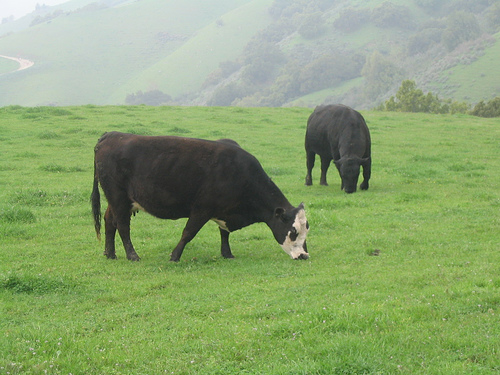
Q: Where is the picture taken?
A: A field.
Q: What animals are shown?
A: Cows.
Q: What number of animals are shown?
A: Two.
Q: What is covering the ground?
A: Grass.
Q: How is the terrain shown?
A: Hilly.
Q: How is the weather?
A: Misty.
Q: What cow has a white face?
A: The left one.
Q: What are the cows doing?
A: Grazing.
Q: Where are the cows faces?
A: In the grass.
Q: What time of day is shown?
A: Afternoon.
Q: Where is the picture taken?
A: A field.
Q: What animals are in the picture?
A: Cows.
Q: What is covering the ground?
A: Grass.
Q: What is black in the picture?
A: Cows.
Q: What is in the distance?
A: Hills.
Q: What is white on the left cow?
A: The face.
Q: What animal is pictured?
A: Cows.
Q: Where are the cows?
A: A field.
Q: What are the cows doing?
A: Eating.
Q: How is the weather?
A: Foggy.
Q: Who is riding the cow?
A: No one.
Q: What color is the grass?
A: Green.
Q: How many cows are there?
A: Two.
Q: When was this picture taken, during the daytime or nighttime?
A: Daytime.